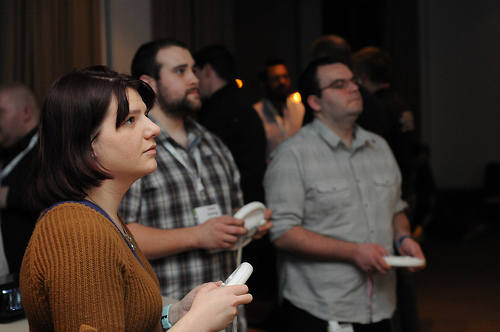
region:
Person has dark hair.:
[33, 70, 123, 172]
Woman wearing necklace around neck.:
[115, 222, 155, 267]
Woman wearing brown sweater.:
[35, 228, 120, 307]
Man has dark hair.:
[136, 35, 201, 95]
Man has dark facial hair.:
[153, 76, 235, 141]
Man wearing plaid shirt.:
[167, 161, 231, 233]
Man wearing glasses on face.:
[319, 68, 371, 95]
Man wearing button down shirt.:
[289, 125, 405, 241]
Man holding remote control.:
[378, 234, 452, 288]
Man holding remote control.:
[217, 189, 272, 263]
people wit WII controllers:
[3, 37, 428, 329]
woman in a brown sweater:
[5, 65, 256, 330]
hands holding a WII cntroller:
[161, 261, 253, 330]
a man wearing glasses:
[261, 57, 426, 329]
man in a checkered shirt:
[123, 38, 272, 330]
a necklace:
[103, 202, 141, 254]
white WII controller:
[378, 251, 429, 273]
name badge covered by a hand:
[180, 145, 233, 251]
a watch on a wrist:
[393, 226, 418, 251]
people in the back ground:
[198, 25, 303, 137]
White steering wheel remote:
[230, 204, 267, 248]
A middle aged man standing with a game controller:
[264, 57, 425, 330]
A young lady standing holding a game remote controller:
[20, 67, 253, 329]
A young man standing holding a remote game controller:
[118, 37, 268, 329]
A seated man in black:
[1, 85, 81, 292]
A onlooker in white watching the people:
[252, 64, 302, 148]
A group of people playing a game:
[18, 39, 427, 330]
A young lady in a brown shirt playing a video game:
[19, 67, 255, 329]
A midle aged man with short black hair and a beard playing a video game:
[120, 38, 272, 330]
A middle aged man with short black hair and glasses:
[261, 59, 428, 330]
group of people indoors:
[6, 0, 497, 330]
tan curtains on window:
[3, 0, 102, 102]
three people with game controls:
[26, 38, 421, 329]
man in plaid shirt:
[133, 32, 270, 327]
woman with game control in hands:
[23, 66, 252, 330]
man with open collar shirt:
[262, 54, 428, 321]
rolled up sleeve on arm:
[265, 149, 351, 251]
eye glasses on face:
[317, 62, 364, 121]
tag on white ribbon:
[165, 142, 222, 224]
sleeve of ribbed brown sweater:
[19, 198, 161, 328]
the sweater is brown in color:
[43, 200, 172, 330]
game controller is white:
[216, 184, 292, 274]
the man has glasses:
[281, 63, 433, 330]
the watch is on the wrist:
[156, 299, 172, 329]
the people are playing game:
[11, 55, 406, 328]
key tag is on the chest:
[167, 155, 234, 240]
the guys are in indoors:
[1, 8, 496, 329]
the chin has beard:
[163, 85, 223, 123]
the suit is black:
[211, 95, 274, 155]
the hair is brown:
[26, 78, 98, 189]